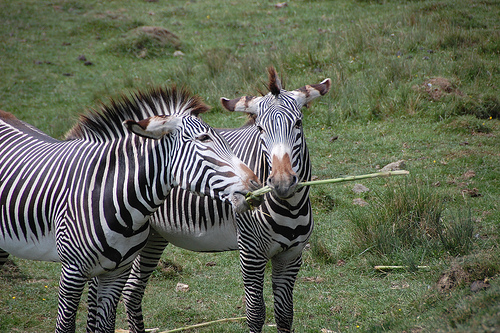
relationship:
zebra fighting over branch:
[0, 85, 263, 332] [245, 158, 411, 200]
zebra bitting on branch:
[0, 85, 263, 332] [245, 158, 411, 200]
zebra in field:
[0, 85, 263, 332] [1, 0, 499, 120]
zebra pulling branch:
[0, 85, 263, 332] [245, 158, 411, 200]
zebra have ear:
[0, 85, 263, 332] [124, 115, 171, 141]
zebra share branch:
[0, 85, 263, 332] [245, 158, 411, 200]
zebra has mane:
[0, 85, 263, 332] [64, 85, 212, 140]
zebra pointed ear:
[0, 85, 263, 332] [124, 115, 171, 141]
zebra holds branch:
[0, 85, 263, 332] [245, 158, 411, 200]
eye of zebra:
[198, 135, 211, 142] [0, 85, 263, 332]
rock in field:
[130, 25, 182, 47] [1, 0, 499, 120]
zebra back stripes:
[0, 85, 263, 332] [2, 113, 63, 144]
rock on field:
[130, 25, 182, 47] [1, 0, 499, 120]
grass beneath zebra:
[2, 306, 56, 330] [0, 85, 263, 332]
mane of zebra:
[64, 85, 212, 140] [0, 85, 263, 332]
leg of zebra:
[54, 252, 84, 332] [0, 85, 263, 332]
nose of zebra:
[234, 160, 261, 195] [0, 85, 263, 332]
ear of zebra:
[124, 115, 171, 141] [0, 85, 263, 332]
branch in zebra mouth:
[245, 158, 411, 200] [232, 190, 260, 207]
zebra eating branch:
[0, 85, 263, 332] [245, 158, 411, 200]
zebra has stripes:
[0, 85, 263, 332] [2, 113, 63, 144]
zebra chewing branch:
[0, 85, 263, 332] [245, 158, 411, 200]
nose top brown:
[234, 160, 261, 195] [244, 166, 250, 172]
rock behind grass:
[130, 25, 182, 47] [105, 40, 179, 67]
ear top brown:
[124, 115, 171, 141] [143, 117, 150, 127]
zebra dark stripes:
[0, 85, 263, 332] [2, 113, 63, 144]